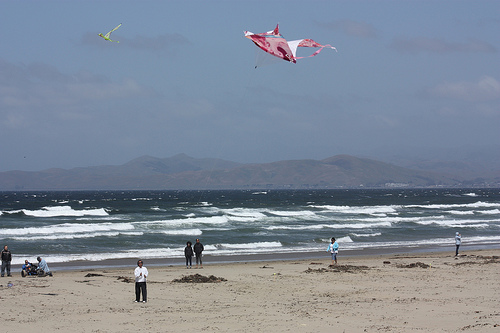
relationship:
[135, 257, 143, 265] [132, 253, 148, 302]
head of man